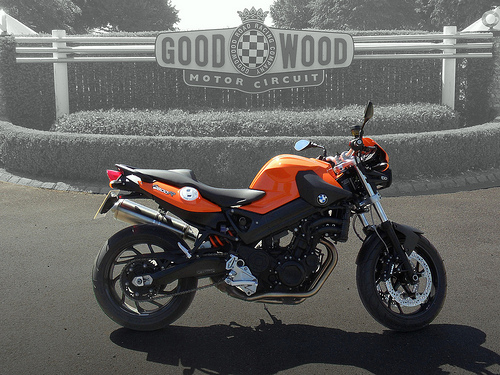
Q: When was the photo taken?
A: Daytime.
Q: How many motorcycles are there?
A: One.